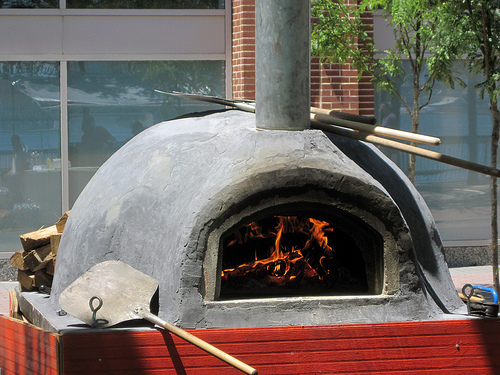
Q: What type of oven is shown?
A: A wood fire oven.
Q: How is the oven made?
A: Of brick and metal.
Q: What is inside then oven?
A: A fire.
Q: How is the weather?
A: Sunny.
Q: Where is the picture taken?
A: Outdoor venue.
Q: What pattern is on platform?
A: Striped.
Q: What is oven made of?
A: Brick.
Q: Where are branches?
A: On tree.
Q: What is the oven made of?
A: Concrete.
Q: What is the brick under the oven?
A: Red brick.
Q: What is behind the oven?
A: Glass window.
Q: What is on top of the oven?
A: A pipe.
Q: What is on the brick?
A: Pizza Spatula.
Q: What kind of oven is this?
A: Pizza oven.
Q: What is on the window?
A: Reflection.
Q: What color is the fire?
A: Orange.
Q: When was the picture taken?
A: During the day.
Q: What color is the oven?
A: Gray.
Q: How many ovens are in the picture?
A: One.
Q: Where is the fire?
A: Inside the oven.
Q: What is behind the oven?
A: Wood.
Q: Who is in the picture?
A: There are no people in the image.